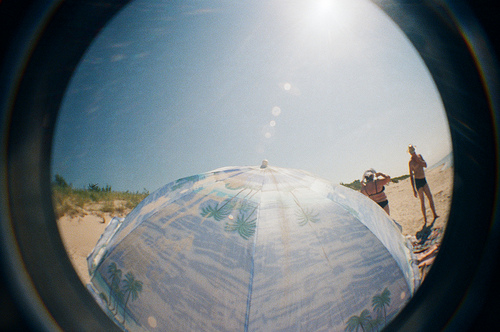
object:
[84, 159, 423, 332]
umbrella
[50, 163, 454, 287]
beach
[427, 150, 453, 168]
water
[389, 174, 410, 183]
grass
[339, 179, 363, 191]
green grass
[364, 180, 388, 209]
bathing suit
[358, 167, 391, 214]
woman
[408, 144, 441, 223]
man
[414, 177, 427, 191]
shorts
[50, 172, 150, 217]
grass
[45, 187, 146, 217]
patch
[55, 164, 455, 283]
sand